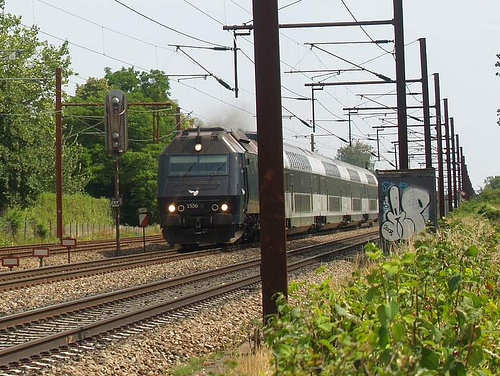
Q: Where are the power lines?
A: Above the train.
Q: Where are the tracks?
A: On the ground.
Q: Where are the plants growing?
A: Near the tracks.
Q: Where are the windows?
A: On the train.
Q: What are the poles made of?
A: Wood.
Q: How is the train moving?
A: Tracks.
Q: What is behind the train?
A: Trees.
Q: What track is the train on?
A: Middle track.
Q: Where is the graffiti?
A: On a power box.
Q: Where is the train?
A: On tracks.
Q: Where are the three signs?
A: By the track.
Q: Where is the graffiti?
A: On sign.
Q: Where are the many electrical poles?
A: Along tracks.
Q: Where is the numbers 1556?
A: On train's nose.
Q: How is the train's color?
A: Black.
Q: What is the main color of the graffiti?
A: White.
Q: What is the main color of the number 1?
A: White.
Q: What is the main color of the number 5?
A: White.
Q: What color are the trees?
A: Green.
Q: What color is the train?
A: Grey.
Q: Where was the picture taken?
A: The tracks.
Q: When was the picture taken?
A: Midday.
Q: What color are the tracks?
A: Brown.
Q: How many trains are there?
A: One.